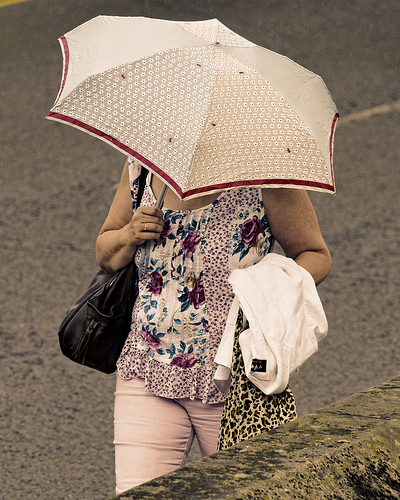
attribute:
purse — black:
[66, 271, 138, 369]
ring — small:
[140, 223, 149, 232]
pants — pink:
[111, 366, 225, 497]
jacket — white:
[212, 252, 328, 397]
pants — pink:
[115, 394, 187, 463]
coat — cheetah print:
[210, 310, 301, 464]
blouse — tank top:
[124, 158, 281, 373]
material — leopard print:
[208, 312, 305, 455]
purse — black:
[57, 164, 149, 374]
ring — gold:
[144, 223, 148, 234]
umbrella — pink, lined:
[54, 13, 355, 203]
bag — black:
[36, 247, 176, 343]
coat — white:
[211, 252, 329, 396]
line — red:
[43, 31, 340, 203]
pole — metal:
[142, 182, 167, 276]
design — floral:
[43, 14, 339, 201]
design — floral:
[116, 153, 274, 403]